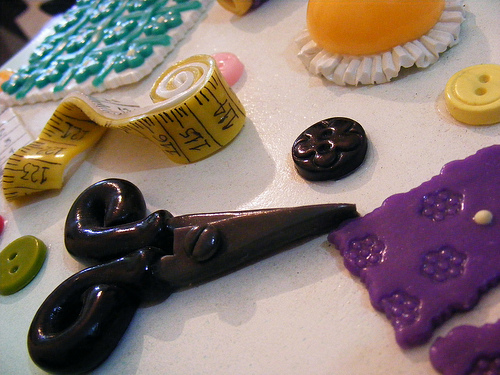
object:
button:
[445, 62, 500, 124]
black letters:
[212, 98, 239, 131]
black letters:
[152, 135, 181, 157]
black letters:
[20, 162, 50, 185]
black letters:
[61, 121, 87, 141]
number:
[213, 98, 239, 130]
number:
[179, 127, 212, 151]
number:
[19, 163, 52, 185]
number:
[60, 121, 89, 140]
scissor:
[28, 177, 361, 375]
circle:
[290, 116, 368, 181]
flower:
[295, 118, 357, 166]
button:
[291, 116, 368, 181]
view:
[252, 297, 337, 355]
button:
[210, 52, 246, 87]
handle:
[25, 245, 168, 373]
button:
[0, 234, 48, 295]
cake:
[0, 0, 499, 375]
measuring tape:
[2, 56, 251, 201]